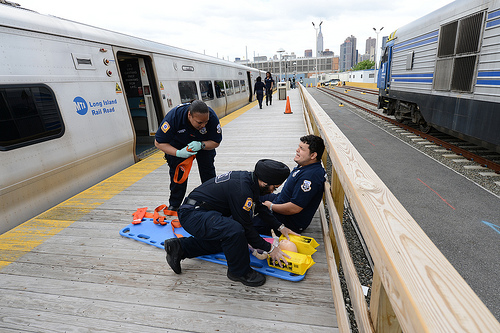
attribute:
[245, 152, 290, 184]
turban — black 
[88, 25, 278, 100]
train — white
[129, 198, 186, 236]
straps — orange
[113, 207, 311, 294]
board — blue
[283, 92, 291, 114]
cone — orange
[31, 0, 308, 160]
train — Silver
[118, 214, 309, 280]
backboard — Blue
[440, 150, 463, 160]
tie — to cross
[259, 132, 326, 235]
man — hurt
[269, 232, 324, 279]
head supports — Yellow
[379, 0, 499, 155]
train — Silver and blue, blue, gray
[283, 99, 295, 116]
cone — orange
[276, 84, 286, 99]
trashcan — distant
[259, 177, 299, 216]
tie — to cross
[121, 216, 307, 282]
life board — blue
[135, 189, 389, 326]
board — blue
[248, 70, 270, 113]
lady — walking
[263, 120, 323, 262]
man — seated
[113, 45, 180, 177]
door — open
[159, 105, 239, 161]
person — wearing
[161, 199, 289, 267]
pants — blue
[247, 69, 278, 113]
woman girl — walking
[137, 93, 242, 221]
woman — gloved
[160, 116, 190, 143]
uniform — blue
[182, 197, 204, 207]
belt — Black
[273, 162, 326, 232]
shirt — blue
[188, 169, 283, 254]
shirt — blue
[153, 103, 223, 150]
shirt — blue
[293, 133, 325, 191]
man — leaning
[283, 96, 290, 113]
cone — Orange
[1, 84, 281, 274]
line — Yellow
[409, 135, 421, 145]
tie — to cross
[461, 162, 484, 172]
tie — to cross